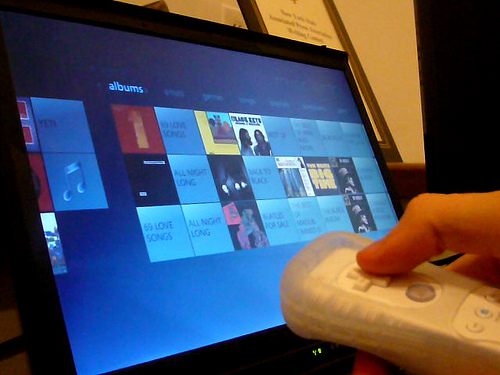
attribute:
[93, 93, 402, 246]
albums — listed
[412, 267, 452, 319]
button — round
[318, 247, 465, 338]
button — remote  button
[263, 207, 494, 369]
remote — used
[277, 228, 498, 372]
remote control — held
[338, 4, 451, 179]
wall — white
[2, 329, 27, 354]
cord — black, behind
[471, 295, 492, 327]
button — blue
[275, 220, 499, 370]
controller — white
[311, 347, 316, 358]
indicator — wireless, blue tooth, lit up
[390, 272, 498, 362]
button — white, blue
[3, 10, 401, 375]
screen — blue